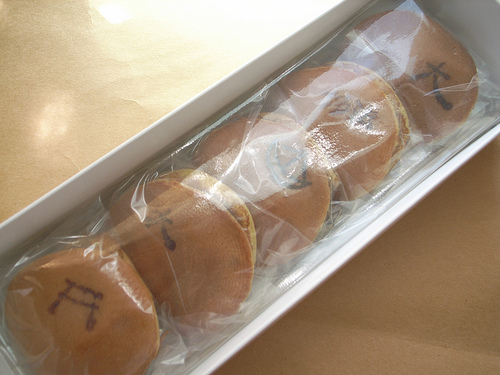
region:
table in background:
[33, 9, 135, 119]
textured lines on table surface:
[105, 92, 153, 117]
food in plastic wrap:
[33, 165, 275, 374]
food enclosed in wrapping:
[0, 68, 413, 341]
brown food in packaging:
[51, 51, 411, 346]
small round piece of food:
[0, 238, 161, 374]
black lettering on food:
[34, 276, 115, 346]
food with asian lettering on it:
[36, 13, 482, 360]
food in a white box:
[0, 30, 467, 355]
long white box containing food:
[19, 54, 438, 374]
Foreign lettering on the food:
[406, 53, 458, 118]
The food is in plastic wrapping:
[3, 5, 485, 370]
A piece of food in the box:
[4, 221, 139, 372]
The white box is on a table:
[12, 14, 495, 371]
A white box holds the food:
[0, 1, 498, 366]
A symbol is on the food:
[40, 278, 142, 341]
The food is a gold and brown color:
[8, 209, 143, 370]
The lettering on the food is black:
[43, 275, 109, 327]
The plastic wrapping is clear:
[33, 13, 483, 365]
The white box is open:
[6, 2, 495, 368]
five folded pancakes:
[10, 11, 491, 368]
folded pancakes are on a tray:
[15, 1, 495, 372]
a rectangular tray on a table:
[0, 1, 496, 356]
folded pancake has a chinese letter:
[375, 10, 485, 126]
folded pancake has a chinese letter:
[284, 66, 415, 176]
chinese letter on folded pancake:
[125, 200, 195, 264]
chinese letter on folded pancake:
[33, 265, 122, 337]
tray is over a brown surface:
[10, 6, 497, 373]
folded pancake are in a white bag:
[8, 0, 489, 372]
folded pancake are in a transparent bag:
[2, 5, 497, 372]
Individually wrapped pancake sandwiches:
[6, 11, 481, 363]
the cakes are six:
[17, 6, 483, 372]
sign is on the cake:
[52, 282, 114, 339]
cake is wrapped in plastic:
[25, 248, 182, 361]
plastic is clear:
[65, 238, 228, 352]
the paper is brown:
[59, 55, 152, 116]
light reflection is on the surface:
[121, 17, 229, 82]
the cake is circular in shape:
[162, 168, 272, 320]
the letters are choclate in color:
[55, 280, 110, 331]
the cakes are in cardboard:
[27, 22, 499, 374]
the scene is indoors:
[6, 89, 496, 374]